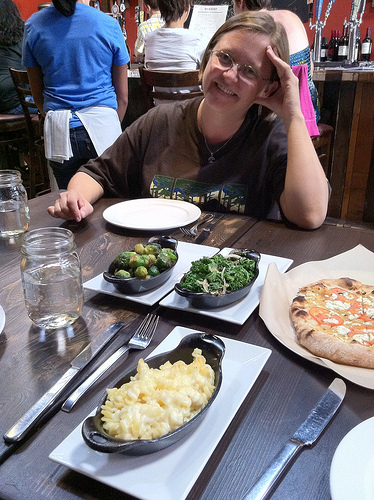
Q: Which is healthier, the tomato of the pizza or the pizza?
A: The tomato is healthier than the pizza.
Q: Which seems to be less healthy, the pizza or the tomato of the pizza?
A: The pizza is less healthy than the tomato.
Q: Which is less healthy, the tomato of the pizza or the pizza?
A: The pizza is less healthy than the tomato.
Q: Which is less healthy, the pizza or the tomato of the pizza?
A: The pizza is less healthy than the tomato.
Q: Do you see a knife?
A: Yes, there is a knife.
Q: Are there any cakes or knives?
A: Yes, there is a knife.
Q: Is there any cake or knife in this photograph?
A: Yes, there is a knife.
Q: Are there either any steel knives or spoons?
A: Yes, there is a steel knife.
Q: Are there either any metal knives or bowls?
A: Yes, there is a metal knife.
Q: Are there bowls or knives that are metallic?
A: Yes, the knife is metallic.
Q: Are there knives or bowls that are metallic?
A: Yes, the knife is metallic.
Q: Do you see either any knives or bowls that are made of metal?
A: Yes, the knife is made of metal.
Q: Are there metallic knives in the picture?
A: Yes, there is a metal knife.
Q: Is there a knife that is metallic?
A: Yes, there is a knife that is metallic.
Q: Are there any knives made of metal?
A: Yes, there is a knife that is made of metal.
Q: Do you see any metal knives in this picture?
A: Yes, there is a knife that is made of metal.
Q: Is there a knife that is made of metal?
A: Yes, there is a knife that is made of metal.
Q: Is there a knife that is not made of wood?
A: Yes, there is a knife that is made of metal.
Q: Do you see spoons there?
A: No, there are no spoons.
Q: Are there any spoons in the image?
A: No, there are no spoons.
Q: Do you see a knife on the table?
A: Yes, there is a knife on the table.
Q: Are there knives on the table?
A: Yes, there is a knife on the table.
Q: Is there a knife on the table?
A: Yes, there is a knife on the table.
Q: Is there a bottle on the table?
A: No, there is a knife on the table.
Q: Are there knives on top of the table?
A: Yes, there is a knife on top of the table.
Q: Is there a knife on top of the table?
A: Yes, there is a knife on top of the table.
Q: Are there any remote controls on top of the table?
A: No, there is a knife on top of the table.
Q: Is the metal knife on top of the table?
A: Yes, the knife is on top of the table.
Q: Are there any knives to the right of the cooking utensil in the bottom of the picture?
A: Yes, there is a knife to the right of the pan.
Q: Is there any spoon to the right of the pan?
A: No, there is a knife to the right of the pan.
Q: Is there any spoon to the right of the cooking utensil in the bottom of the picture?
A: No, there is a knife to the right of the pan.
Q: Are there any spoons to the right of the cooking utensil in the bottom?
A: No, there is a knife to the right of the pan.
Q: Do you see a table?
A: Yes, there is a table.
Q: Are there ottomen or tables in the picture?
A: Yes, there is a table.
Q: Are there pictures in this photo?
A: No, there are no pictures.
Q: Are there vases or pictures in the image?
A: No, there are no pictures or vases.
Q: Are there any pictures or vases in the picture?
A: No, there are no pictures or vases.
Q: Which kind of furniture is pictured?
A: The furniture is a table.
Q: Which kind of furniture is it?
A: The piece of furniture is a table.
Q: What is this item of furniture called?
A: That is a table.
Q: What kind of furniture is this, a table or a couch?
A: That is a table.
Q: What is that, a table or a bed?
A: That is a table.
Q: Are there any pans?
A: Yes, there is a pan.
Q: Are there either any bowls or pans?
A: Yes, there is a pan.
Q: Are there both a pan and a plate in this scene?
A: Yes, there are both a pan and a plate.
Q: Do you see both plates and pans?
A: Yes, there are both a pan and a plate.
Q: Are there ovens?
A: No, there are no ovens.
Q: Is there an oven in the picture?
A: No, there are no ovens.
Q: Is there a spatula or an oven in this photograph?
A: No, there are no ovens or spatulas.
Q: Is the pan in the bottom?
A: Yes, the pan is in the bottom of the image.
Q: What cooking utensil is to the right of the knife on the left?
A: The cooking utensil is a pan.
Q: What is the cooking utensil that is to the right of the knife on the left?
A: The cooking utensil is a pan.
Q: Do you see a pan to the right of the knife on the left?
A: Yes, there is a pan to the right of the knife.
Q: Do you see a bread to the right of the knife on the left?
A: No, there is a pan to the right of the knife.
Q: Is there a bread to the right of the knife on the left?
A: No, there is a pan to the right of the knife.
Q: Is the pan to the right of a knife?
A: Yes, the pan is to the right of a knife.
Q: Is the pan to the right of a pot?
A: No, the pan is to the right of a knife.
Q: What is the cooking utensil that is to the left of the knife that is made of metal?
A: The cooking utensil is a pan.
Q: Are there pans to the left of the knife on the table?
A: Yes, there is a pan to the left of the knife.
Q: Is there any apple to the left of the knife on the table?
A: No, there is a pan to the left of the knife.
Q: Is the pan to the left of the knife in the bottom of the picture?
A: Yes, the pan is to the left of the knife.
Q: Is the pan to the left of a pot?
A: No, the pan is to the left of the knife.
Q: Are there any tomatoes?
A: Yes, there is a tomato.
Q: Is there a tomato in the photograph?
A: Yes, there is a tomato.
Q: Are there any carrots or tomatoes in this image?
A: Yes, there is a tomato.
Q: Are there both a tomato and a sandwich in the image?
A: No, there is a tomato but no sandwiches.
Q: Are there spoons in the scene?
A: No, there are no spoons.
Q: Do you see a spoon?
A: No, there are no spoons.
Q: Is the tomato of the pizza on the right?
A: Yes, the tomato is on the right of the image.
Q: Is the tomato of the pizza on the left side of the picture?
A: No, the tomato is on the right of the image.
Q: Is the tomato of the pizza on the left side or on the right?
A: The tomato is on the right of the image.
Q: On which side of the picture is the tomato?
A: The tomato is on the right of the image.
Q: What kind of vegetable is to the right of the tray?
A: The vegetable is a tomato.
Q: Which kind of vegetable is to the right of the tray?
A: The vegetable is a tomato.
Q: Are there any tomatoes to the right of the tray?
A: Yes, there is a tomato to the right of the tray.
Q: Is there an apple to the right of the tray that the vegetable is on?
A: No, there is a tomato to the right of the tray.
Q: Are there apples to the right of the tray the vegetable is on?
A: No, there is a tomato to the right of the tray.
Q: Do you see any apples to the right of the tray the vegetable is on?
A: No, there is a tomato to the right of the tray.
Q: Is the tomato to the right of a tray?
A: Yes, the tomato is to the right of a tray.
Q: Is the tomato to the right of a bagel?
A: No, the tomato is to the right of a tray.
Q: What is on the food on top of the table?
A: The tomato is on the pizza.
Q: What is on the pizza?
A: The tomato is on the pizza.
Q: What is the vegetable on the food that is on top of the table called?
A: The vegetable is a tomato.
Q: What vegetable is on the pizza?
A: The vegetable is a tomato.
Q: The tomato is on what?
A: The tomato is on the pizza.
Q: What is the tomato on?
A: The tomato is on the pizza.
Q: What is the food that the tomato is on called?
A: The food is a pizza.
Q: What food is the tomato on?
A: The tomato is on the pizza.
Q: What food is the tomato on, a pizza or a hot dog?
A: The tomato is on a pizza.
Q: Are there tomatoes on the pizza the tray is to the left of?
A: Yes, there is a tomato on the pizza.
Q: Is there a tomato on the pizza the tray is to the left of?
A: Yes, there is a tomato on the pizza.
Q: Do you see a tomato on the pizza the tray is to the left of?
A: Yes, there is a tomato on the pizza.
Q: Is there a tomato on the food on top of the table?
A: Yes, there is a tomato on the pizza.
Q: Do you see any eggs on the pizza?
A: No, there is a tomato on the pizza.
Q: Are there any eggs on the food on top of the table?
A: No, there is a tomato on the pizza.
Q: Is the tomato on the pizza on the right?
A: Yes, the tomato is on the pizza.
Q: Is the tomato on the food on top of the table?
A: Yes, the tomato is on the pizza.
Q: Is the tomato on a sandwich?
A: No, the tomato is on the pizza.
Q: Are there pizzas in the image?
A: Yes, there is a pizza.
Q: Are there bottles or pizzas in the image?
A: Yes, there is a pizza.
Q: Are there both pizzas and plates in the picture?
A: Yes, there are both a pizza and a plate.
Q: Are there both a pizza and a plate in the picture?
A: Yes, there are both a pizza and a plate.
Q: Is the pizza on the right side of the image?
A: Yes, the pizza is on the right of the image.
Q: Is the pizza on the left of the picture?
A: No, the pizza is on the right of the image.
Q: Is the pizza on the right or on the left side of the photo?
A: The pizza is on the right of the image.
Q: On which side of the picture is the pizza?
A: The pizza is on the right of the image.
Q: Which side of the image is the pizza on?
A: The pizza is on the right of the image.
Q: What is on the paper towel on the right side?
A: The pizza is on the paper towel.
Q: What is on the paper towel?
A: The pizza is on the paper towel.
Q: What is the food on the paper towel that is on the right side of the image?
A: The food is a pizza.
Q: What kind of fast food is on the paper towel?
A: The food is a pizza.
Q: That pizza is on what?
A: The pizza is on the paper towel.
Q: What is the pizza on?
A: The pizza is on the paper towel.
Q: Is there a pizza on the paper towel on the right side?
A: Yes, there is a pizza on the paper towel.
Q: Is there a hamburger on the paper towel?
A: No, there is a pizza on the paper towel.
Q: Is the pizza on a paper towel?
A: Yes, the pizza is on a paper towel.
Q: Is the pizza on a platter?
A: No, the pizza is on a paper towel.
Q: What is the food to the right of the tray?
A: The food is a pizza.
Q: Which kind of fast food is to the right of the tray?
A: The food is a pizza.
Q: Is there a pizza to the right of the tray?
A: Yes, there is a pizza to the right of the tray.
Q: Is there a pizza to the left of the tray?
A: No, the pizza is to the right of the tray.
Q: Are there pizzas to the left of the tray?
A: No, the pizza is to the right of the tray.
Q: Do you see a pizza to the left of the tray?
A: No, the pizza is to the right of the tray.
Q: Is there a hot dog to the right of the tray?
A: No, there is a pizza to the right of the tray.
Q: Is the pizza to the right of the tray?
A: Yes, the pizza is to the right of the tray.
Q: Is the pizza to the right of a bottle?
A: No, the pizza is to the right of the tray.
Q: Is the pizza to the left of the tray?
A: No, the pizza is to the right of the tray.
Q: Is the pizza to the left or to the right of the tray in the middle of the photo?
A: The pizza is to the right of the tray.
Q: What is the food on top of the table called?
A: The food is a pizza.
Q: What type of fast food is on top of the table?
A: The food is a pizza.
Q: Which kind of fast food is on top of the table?
A: The food is a pizza.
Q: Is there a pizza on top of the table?
A: Yes, there is a pizza on top of the table.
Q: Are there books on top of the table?
A: No, there is a pizza on top of the table.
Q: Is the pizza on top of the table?
A: Yes, the pizza is on top of the table.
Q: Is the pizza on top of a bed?
A: No, the pizza is on top of the table.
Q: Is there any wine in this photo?
A: No, there is no wine.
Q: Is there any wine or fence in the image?
A: No, there are no wine or fences.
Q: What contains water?
A: The glass contains water.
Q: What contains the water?
A: The glass contains water.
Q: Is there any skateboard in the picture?
A: No, there are no skateboards.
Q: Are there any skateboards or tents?
A: No, there are no skateboards or tents.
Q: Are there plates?
A: Yes, there is a plate.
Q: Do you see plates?
A: Yes, there is a plate.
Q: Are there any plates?
A: Yes, there is a plate.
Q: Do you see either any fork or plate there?
A: Yes, there is a plate.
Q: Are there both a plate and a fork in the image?
A: Yes, there are both a plate and a fork.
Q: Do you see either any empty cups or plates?
A: Yes, there is an empty plate.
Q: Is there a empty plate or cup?
A: Yes, there is an empty plate.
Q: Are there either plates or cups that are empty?
A: Yes, the plate is empty.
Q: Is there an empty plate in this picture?
A: Yes, there is an empty plate.